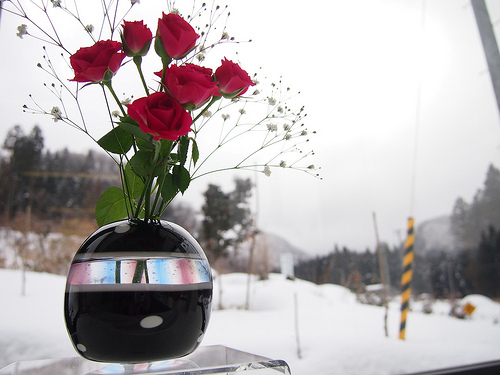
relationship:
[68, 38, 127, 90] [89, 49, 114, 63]
flower has petal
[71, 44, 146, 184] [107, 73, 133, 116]
flower has stem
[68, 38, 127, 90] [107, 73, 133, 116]
flower has stem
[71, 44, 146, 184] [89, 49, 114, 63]
flower has petal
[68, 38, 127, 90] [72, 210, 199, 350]
flower in vase